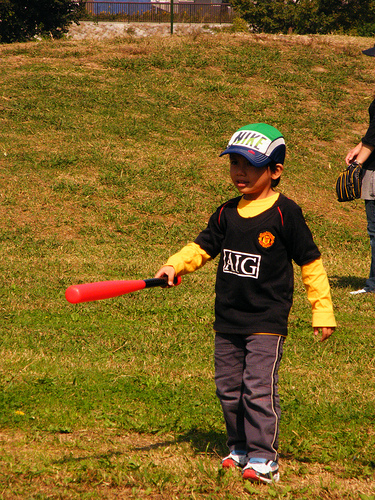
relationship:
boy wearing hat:
[155, 115, 346, 488] [217, 117, 290, 169]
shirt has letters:
[156, 194, 346, 330] [218, 245, 266, 282]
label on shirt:
[250, 222, 282, 256] [156, 194, 346, 330]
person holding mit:
[333, 35, 374, 296] [330, 150, 369, 206]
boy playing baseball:
[155, 115, 346, 488] [39, 217, 195, 329]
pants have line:
[206, 320, 288, 460] [266, 333, 282, 465]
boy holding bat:
[155, 115, 346, 488] [63, 273, 185, 307]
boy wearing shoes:
[155, 115, 346, 488] [215, 443, 289, 485]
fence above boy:
[37, 2, 253, 38] [155, 115, 346, 488]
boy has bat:
[155, 115, 346, 488] [63, 273, 185, 307]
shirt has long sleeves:
[156, 194, 346, 330] [294, 254, 346, 331]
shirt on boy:
[156, 194, 346, 330] [155, 115, 346, 488]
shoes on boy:
[215, 443, 289, 485] [155, 115, 346, 488]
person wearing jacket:
[333, 35, 374, 296] [362, 93, 374, 175]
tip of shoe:
[213, 450, 264, 488] [242, 453, 287, 489]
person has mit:
[333, 35, 374, 296] [330, 150, 369, 206]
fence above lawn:
[37, 2, 253, 38] [1, 35, 373, 498]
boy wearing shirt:
[155, 115, 346, 488] [156, 194, 346, 330]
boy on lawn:
[155, 115, 346, 488] [1, 35, 373, 498]